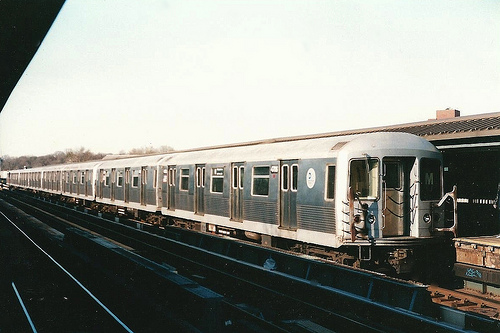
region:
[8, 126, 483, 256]
A long train parked on the tracks.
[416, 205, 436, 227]
A light on the front of the train.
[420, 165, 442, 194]
The letter M inside the train.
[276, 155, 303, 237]
Train doors on the outside of the train.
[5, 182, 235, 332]
Empty, metal train tracks.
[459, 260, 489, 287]
Graffiti on the train tracks.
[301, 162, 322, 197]
An emblem on the side of a train.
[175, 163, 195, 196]
A window on the side of the train.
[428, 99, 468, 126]
Chimney on top of the building.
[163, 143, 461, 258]
A metal subway car.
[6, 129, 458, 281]
A silver and white train.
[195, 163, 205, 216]
A door on a train.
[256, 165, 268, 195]
A window on a train.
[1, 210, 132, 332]
A dark train rail.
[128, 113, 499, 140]
A brown colored roof of a train station.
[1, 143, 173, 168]
Brown trees in the background.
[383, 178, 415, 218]
Chains on a train.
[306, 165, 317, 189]
A sign on a train.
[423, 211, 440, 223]
Lights on a train.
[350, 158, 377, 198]
A front window of a train.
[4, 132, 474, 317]
a train on railroad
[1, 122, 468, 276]
train is white and tan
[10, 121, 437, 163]
roof of train is white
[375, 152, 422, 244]
a door on front a train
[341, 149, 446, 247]
two windows on side doors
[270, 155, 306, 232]
a door of a train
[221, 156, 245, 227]
a door of a train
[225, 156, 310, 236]
a window between two doors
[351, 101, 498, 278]
train in front a train station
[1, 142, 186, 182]
trees behind the train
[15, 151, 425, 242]
long silver metro train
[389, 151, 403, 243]
doorway in front of train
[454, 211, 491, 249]
boarding platform on right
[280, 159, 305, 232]
electronic sliding doors on side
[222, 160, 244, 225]
electronic sliding doors on side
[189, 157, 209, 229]
electronic sliding doors on side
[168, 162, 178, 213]
electronic sliding doors on side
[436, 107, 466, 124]
building chimney in background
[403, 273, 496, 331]
rusty rails below train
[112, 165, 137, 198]
electronic sliding doors on side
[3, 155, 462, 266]
a long silver train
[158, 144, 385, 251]
each train car has 4 doors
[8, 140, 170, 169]
trees tops can be seen in the distance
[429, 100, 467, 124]
a small portion of a chimney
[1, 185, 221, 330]
empty tracks alongside train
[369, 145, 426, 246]
door at the end of the train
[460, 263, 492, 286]
small area of graffiti on rail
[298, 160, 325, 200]
white circle on side of train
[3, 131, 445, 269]
a very long passenger train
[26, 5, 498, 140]
a clear white sky